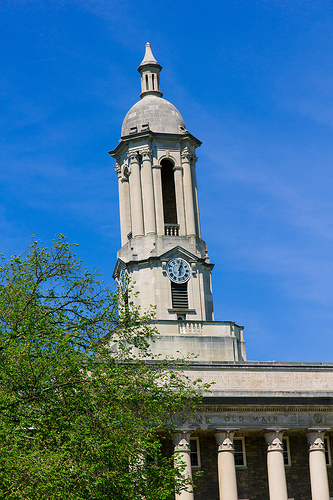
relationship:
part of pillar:
[135, 45, 165, 90] [116, 60, 216, 288]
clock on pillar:
[165, 256, 191, 285] [116, 60, 216, 288]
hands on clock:
[178, 262, 183, 271] [172, 249, 197, 293]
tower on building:
[115, 71, 237, 368] [104, 49, 312, 418]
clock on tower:
[172, 249, 197, 293] [115, 71, 237, 368]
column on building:
[175, 152, 210, 237] [104, 49, 312, 418]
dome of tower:
[122, 99, 187, 136] [115, 71, 237, 368]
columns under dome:
[104, 140, 208, 242] [122, 99, 187, 136]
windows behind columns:
[232, 437, 255, 484] [104, 140, 208, 242]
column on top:
[175, 152, 210, 237] [139, 45, 167, 70]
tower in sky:
[115, 71, 237, 368] [27, 24, 312, 191]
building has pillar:
[104, 49, 312, 418] [116, 60, 216, 288]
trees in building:
[23, 266, 165, 451] [104, 49, 312, 418]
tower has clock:
[115, 71, 237, 368] [172, 249, 197, 293]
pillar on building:
[116, 60, 216, 288] [104, 49, 312, 418]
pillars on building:
[119, 153, 153, 229] [104, 49, 312, 418]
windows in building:
[232, 437, 255, 484] [104, 49, 312, 418]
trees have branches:
[23, 266, 165, 451] [40, 252, 79, 289]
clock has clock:
[172, 249, 197, 293] [165, 256, 191, 285]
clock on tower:
[172, 249, 197, 293] [91, 71, 247, 363]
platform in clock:
[157, 214, 181, 235] [172, 249, 197, 293]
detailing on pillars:
[122, 149, 154, 159] [119, 153, 153, 229]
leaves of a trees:
[38, 298, 96, 378] [0, 230, 203, 500]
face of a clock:
[166, 258, 192, 283] [172, 249, 197, 293]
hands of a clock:
[179, 260, 186, 273] [172, 249, 197, 293]